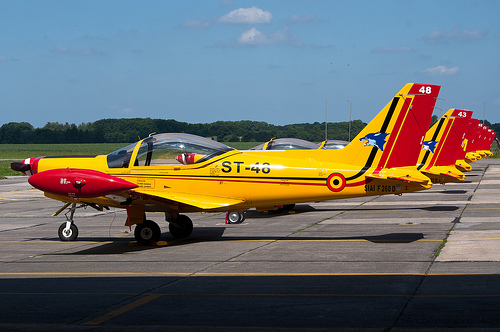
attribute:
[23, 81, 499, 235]
planes — red, yellow, off, stopped, parked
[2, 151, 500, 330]
runway — close, grey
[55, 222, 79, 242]
wheel — black, white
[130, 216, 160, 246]
wheel — black, white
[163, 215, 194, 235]
wheel — black, white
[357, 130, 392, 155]
wolf — blue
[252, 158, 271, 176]
number — black, painted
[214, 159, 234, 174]
letter — black, painted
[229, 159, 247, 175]
letter — black, painted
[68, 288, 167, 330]
line — painted, yellow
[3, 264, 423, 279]
line — painted, yellow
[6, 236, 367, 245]
line — painted, yellow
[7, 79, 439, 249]
plane — yellow, red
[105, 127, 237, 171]
window — cockpit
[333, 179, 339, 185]
dot — black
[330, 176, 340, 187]
circle — yellow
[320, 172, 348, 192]
circle — red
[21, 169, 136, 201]
engine — red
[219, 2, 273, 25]
cloud — white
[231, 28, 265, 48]
cloud — white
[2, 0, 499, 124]
sky — blue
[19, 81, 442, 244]
jet — yellow, red, military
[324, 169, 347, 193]
design — bullseye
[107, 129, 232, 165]
glass — clear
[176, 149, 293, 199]
logo — wolf